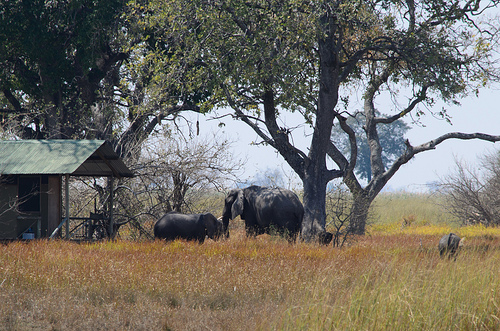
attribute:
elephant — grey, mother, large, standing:
[223, 179, 300, 233]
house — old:
[5, 142, 123, 242]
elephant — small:
[141, 210, 215, 241]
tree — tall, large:
[255, 30, 355, 184]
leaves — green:
[295, 65, 310, 82]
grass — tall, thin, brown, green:
[209, 257, 263, 297]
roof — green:
[9, 140, 92, 173]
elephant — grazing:
[399, 215, 414, 231]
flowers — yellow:
[204, 243, 232, 260]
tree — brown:
[329, 182, 342, 191]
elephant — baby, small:
[431, 230, 462, 257]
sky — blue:
[454, 108, 490, 122]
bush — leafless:
[330, 198, 358, 250]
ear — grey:
[230, 195, 245, 218]